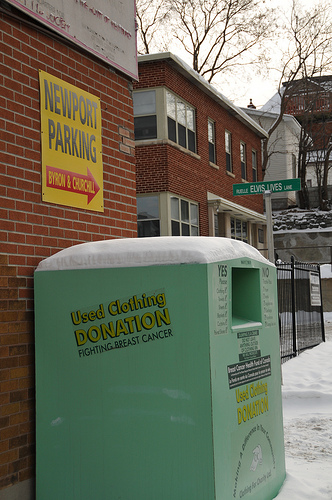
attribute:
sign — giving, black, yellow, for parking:
[36, 68, 108, 215]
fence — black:
[276, 256, 324, 302]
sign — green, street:
[231, 164, 307, 204]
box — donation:
[31, 235, 286, 498]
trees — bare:
[177, 5, 275, 90]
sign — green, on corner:
[29, 68, 134, 238]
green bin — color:
[48, 281, 262, 499]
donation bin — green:
[48, 238, 266, 461]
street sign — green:
[226, 171, 310, 207]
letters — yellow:
[56, 287, 186, 350]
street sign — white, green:
[227, 176, 310, 198]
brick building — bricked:
[0, 0, 138, 497]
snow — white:
[287, 351, 326, 423]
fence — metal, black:
[276, 255, 326, 362]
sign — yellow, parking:
[29, 63, 113, 210]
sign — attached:
[308, 267, 326, 311]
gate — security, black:
[278, 253, 317, 351]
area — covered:
[298, 351, 327, 497]